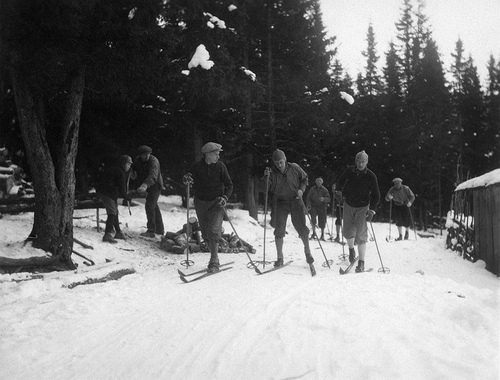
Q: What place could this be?
A: It is a path.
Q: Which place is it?
A: It is a path.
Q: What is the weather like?
A: It is cloudy.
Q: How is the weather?
A: It is cloudy.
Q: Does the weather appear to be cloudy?
A: Yes, it is cloudy.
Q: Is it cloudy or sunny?
A: It is cloudy.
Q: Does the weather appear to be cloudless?
A: No, it is cloudy.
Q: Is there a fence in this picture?
A: No, there are no fences.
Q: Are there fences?
A: No, there are no fences.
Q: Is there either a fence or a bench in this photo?
A: No, there are no fences or benches.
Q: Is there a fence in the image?
A: No, there are no fences.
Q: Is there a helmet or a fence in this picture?
A: No, there are no fences or helmets.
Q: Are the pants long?
A: Yes, the pants are long.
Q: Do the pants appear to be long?
A: Yes, the pants are long.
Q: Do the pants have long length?
A: Yes, the pants are long.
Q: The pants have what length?
A: The pants are long.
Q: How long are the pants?
A: The pants are long.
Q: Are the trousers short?
A: No, the trousers are long.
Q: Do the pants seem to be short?
A: No, the pants are long.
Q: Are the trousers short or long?
A: The trousers are long.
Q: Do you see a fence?
A: No, there are no fences.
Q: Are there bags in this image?
A: No, there are no bags.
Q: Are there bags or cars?
A: No, there are no bags or cars.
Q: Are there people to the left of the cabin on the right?
A: Yes, there is a person to the left of the cabin.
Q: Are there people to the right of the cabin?
A: No, the person is to the left of the cabin.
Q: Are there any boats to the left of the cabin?
A: No, there is a person to the left of the cabin.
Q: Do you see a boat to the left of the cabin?
A: No, there is a person to the left of the cabin.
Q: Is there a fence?
A: No, there are no fences.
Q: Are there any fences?
A: No, there are no fences.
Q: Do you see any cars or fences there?
A: No, there are no fences or cars.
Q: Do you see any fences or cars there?
A: No, there are no fences or cars.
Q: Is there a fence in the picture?
A: No, there are no fences.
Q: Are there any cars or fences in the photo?
A: No, there are no fences or cars.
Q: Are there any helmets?
A: No, there are no helmets.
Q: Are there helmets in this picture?
A: No, there are no helmets.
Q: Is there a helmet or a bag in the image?
A: No, there are no helmets or bags.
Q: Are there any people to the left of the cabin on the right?
A: Yes, there is a person to the left of the cabin.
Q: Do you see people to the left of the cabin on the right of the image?
A: Yes, there is a person to the left of the cabin.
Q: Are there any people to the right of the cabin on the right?
A: No, the person is to the left of the cabin.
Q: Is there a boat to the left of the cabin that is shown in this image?
A: No, there is a person to the left of the cabin.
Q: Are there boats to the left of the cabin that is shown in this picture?
A: No, there is a person to the left of the cabin.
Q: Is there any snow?
A: Yes, there is snow.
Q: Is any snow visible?
A: Yes, there is snow.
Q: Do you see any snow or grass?
A: Yes, there is snow.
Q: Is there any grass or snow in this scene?
A: Yes, there is snow.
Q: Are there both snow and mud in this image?
A: No, there is snow but no mud.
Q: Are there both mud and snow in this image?
A: No, there is snow but no mud.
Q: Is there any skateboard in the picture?
A: No, there are no skateboards.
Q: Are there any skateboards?
A: No, there are no skateboards.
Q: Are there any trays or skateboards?
A: No, there are no skateboards or trays.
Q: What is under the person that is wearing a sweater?
A: The snow is under the person.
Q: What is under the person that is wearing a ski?
A: The snow is under the person.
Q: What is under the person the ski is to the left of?
A: The snow is under the person.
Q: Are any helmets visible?
A: No, there are no helmets.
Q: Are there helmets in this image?
A: No, there are no helmets.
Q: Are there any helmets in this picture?
A: No, there are no helmets.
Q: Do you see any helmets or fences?
A: No, there are no helmets or fences.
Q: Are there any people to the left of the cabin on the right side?
A: Yes, there is a person to the left of the cabin.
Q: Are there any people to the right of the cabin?
A: No, the person is to the left of the cabin.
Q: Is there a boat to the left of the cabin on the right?
A: No, there is a person to the left of the cabin.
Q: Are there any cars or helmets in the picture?
A: No, there are no helmets or cars.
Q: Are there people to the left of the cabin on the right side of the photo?
A: Yes, there is a person to the left of the cabin.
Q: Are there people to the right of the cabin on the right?
A: No, the person is to the left of the cabin.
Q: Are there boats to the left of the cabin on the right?
A: No, there is a person to the left of the cabin.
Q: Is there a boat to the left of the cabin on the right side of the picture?
A: No, there is a person to the left of the cabin.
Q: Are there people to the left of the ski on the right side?
A: Yes, there is a person to the left of the ski.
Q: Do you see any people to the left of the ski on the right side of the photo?
A: Yes, there is a person to the left of the ski.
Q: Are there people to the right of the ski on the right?
A: No, the person is to the left of the ski.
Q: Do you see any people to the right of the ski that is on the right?
A: No, the person is to the left of the ski.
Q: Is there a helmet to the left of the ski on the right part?
A: No, there is a person to the left of the ski.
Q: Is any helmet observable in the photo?
A: No, there are no helmets.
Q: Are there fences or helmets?
A: No, there are no helmets or fences.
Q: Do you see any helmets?
A: No, there are no helmets.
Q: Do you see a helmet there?
A: No, there are no helmets.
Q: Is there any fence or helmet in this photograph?
A: No, there are no helmets or fences.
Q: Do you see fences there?
A: No, there are no fences.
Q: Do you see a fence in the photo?
A: No, there are no fences.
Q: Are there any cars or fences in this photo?
A: No, there are no fences or cars.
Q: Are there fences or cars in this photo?
A: No, there are no fences or cars.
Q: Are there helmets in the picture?
A: No, there are no helmets.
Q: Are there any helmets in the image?
A: No, there are no helmets.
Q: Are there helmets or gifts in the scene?
A: No, there are no helmets or gifts.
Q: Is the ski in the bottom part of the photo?
A: Yes, the ski is in the bottom of the image.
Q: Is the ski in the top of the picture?
A: No, the ski is in the bottom of the image.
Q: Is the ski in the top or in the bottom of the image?
A: The ski is in the bottom of the image.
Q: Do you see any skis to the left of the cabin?
A: Yes, there is a ski to the left of the cabin.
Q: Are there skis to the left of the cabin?
A: Yes, there is a ski to the left of the cabin.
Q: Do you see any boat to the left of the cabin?
A: No, there is a ski to the left of the cabin.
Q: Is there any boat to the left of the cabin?
A: No, there is a ski to the left of the cabin.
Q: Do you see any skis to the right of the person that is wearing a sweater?
A: Yes, there is a ski to the right of the person.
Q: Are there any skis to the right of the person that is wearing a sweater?
A: Yes, there is a ski to the right of the person.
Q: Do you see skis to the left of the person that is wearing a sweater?
A: No, the ski is to the right of the person.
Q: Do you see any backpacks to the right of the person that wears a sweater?
A: No, there is a ski to the right of the person.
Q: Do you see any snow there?
A: Yes, there is snow.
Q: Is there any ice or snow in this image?
A: Yes, there is snow.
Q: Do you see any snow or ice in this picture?
A: Yes, there is snow.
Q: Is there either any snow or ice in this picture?
A: Yes, there is snow.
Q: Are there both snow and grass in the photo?
A: No, there is snow but no grass.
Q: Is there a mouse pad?
A: No, there are no mouse pads.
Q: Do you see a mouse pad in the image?
A: No, there are no mouse pads.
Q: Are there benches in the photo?
A: No, there are no benches.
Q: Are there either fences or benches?
A: No, there are no benches or fences.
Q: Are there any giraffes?
A: No, there are no giraffes.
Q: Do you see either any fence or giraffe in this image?
A: No, there are no giraffes or fences.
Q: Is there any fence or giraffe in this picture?
A: No, there are no giraffes or fences.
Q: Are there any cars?
A: No, there are no cars.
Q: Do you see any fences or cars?
A: No, there are no cars or fences.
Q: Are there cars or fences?
A: No, there are no cars or fences.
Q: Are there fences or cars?
A: No, there are no cars or fences.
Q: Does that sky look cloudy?
A: Yes, the sky is cloudy.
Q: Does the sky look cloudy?
A: Yes, the sky is cloudy.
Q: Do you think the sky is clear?
A: No, the sky is cloudy.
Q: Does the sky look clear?
A: No, the sky is cloudy.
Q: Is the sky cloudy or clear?
A: The sky is cloudy.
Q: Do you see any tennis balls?
A: No, there are no tennis balls.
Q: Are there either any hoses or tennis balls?
A: No, there are no tennis balls or hoses.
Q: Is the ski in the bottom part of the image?
A: Yes, the ski is in the bottom of the image.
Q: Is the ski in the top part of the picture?
A: No, the ski is in the bottom of the image.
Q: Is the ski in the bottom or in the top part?
A: The ski is in the bottom of the image.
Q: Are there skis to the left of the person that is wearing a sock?
A: Yes, there is a ski to the left of the person.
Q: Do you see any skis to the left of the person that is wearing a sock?
A: Yes, there is a ski to the left of the person.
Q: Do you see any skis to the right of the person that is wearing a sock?
A: No, the ski is to the left of the person.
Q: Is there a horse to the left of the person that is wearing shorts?
A: No, there is a ski to the left of the person.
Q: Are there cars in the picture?
A: No, there are no cars.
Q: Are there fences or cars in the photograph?
A: No, there are no cars or fences.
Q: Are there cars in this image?
A: No, there are no cars.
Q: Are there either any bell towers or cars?
A: No, there are no cars or bell towers.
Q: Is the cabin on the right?
A: Yes, the cabin is on the right of the image.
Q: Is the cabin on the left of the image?
A: No, the cabin is on the right of the image.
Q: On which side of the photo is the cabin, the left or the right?
A: The cabin is on the right of the image.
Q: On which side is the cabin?
A: The cabin is on the right of the image.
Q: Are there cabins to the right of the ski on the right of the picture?
A: Yes, there is a cabin to the right of the ski.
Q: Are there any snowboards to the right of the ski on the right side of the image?
A: No, there is a cabin to the right of the ski.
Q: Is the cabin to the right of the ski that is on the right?
A: Yes, the cabin is to the right of the ski.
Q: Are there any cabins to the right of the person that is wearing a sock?
A: Yes, there is a cabin to the right of the person.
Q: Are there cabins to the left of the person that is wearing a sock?
A: No, the cabin is to the right of the person.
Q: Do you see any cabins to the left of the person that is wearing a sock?
A: No, the cabin is to the right of the person.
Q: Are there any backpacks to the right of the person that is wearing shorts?
A: No, there is a cabin to the right of the person.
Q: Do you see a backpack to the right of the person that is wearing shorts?
A: No, there is a cabin to the right of the person.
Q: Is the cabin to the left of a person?
A: No, the cabin is to the right of a person.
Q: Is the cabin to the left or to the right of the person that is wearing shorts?
A: The cabin is to the right of the person.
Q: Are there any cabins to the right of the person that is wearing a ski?
A: Yes, there is a cabin to the right of the person.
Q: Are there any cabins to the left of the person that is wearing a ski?
A: No, the cabin is to the right of the person.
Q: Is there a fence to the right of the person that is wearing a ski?
A: No, there is a cabin to the right of the person.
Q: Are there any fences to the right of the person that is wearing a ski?
A: No, there is a cabin to the right of the person.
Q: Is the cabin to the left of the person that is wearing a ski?
A: No, the cabin is to the right of the person.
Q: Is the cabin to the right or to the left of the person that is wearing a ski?
A: The cabin is to the right of the person.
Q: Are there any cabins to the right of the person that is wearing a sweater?
A: Yes, there is a cabin to the right of the person.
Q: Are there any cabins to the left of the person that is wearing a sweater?
A: No, the cabin is to the right of the person.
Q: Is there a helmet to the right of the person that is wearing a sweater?
A: No, there is a cabin to the right of the person.